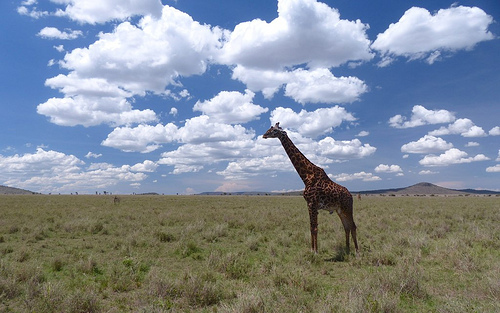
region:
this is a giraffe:
[255, 115, 375, 262]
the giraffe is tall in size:
[260, 121, 358, 263]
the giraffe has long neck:
[268, 121, 312, 181]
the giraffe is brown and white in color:
[264, 118, 356, 266]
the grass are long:
[1, 192, 288, 311]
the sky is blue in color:
[5, 53, 37, 125]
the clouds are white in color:
[130, 22, 350, 67]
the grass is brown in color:
[26, 215, 276, 307]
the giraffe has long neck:
[307, 212, 352, 253]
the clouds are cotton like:
[96, 17, 356, 109]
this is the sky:
[6, 42, 33, 113]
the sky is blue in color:
[433, 67, 495, 94]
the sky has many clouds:
[139, 19, 475, 59]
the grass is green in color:
[147, 200, 237, 234]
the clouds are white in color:
[86, 55, 112, 110]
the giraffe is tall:
[255, 118, 357, 248]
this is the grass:
[176, 206, 282, 269]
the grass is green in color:
[212, 202, 283, 232]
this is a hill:
[404, 181, 446, 193]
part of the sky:
[396, 75, 438, 100]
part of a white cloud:
[298, 74, 344, 109]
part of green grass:
[207, 253, 274, 281]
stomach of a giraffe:
[319, 190, 337, 206]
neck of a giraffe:
[286, 145, 305, 175]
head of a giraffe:
[263, 122, 286, 141]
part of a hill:
[409, 173, 442, 191]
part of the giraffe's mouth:
[258, 132, 271, 141]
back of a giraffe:
[314, 170, 345, 189]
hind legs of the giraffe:
[323, 210, 360, 242]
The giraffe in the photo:
[264, 119, 366, 261]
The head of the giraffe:
[260, 121, 282, 139]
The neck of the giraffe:
[280, 134, 312, 180]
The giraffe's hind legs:
[339, 186, 362, 254]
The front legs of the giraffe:
[302, 187, 323, 255]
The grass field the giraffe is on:
[1, 196, 499, 311]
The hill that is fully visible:
[387, 175, 457, 196]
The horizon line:
[2, 181, 499, 198]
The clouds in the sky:
[1, 0, 495, 185]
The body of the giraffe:
[301, 164, 356, 213]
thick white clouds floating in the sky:
[113, 34, 282, 94]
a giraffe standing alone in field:
[248, 109, 395, 280]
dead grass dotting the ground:
[29, 201, 174, 293]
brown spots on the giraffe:
[307, 174, 337, 205]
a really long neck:
[280, 134, 311, 170]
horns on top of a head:
[274, 121, 285, 131]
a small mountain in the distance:
[406, 180, 445, 193]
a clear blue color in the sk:
[14, 43, 36, 92]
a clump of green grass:
[183, 246, 202, 258]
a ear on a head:
[279, 126, 294, 136]